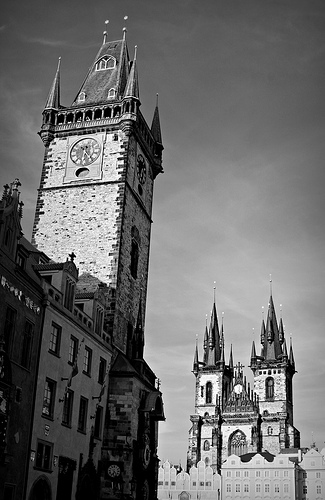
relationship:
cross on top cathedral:
[233, 361, 245, 377] [186, 270, 301, 472]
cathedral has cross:
[186, 270, 301, 472] [233, 361, 245, 377]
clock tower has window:
[29, 12, 167, 359] [123, 231, 142, 282]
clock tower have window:
[29, 12, 167, 359] [123, 231, 142, 282]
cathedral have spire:
[186, 270, 301, 472] [212, 279, 218, 305]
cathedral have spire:
[186, 270, 301, 472] [268, 272, 274, 298]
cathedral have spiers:
[186, 270, 301, 472] [122, 15, 129, 40]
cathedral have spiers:
[186, 270, 301, 472] [102, 19, 110, 44]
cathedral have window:
[12, 253, 187, 473] [35, 316, 74, 359]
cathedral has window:
[12, 253, 187, 473] [35, 316, 74, 359]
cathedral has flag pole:
[0, 25, 165, 499] [60, 337, 86, 406]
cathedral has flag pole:
[0, 25, 165, 499] [90, 347, 120, 401]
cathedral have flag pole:
[0, 25, 165, 499] [60, 337, 86, 406]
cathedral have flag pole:
[0, 25, 165, 499] [90, 347, 120, 401]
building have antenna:
[187, 297, 232, 469] [211, 286, 216, 305]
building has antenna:
[187, 297, 232, 469] [211, 286, 216, 305]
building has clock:
[34, 15, 165, 352] [69, 136, 102, 167]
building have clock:
[34, 15, 165, 352] [69, 136, 102, 167]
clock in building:
[69, 136, 102, 167] [34, 15, 165, 352]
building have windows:
[212, 441, 322, 498] [224, 470, 291, 497]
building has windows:
[212, 441, 322, 498] [224, 470, 291, 497]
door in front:
[227, 428, 247, 454] [187, 272, 284, 468]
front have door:
[187, 272, 284, 468] [227, 428, 247, 454]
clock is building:
[69, 136, 102, 167] [29, 15, 165, 356]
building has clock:
[29, 15, 165, 356] [69, 136, 102, 167]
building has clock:
[29, 15, 165, 356] [134, 154, 147, 185]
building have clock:
[29, 15, 165, 356] [69, 136, 102, 167]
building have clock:
[29, 15, 165, 356] [134, 154, 147, 185]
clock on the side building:
[135, 153, 152, 186] [29, 15, 165, 356]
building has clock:
[29, 15, 165, 356] [135, 153, 152, 186]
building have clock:
[29, 15, 165, 356] [135, 153, 152, 186]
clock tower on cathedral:
[29, 12, 167, 359] [0, 25, 165, 499]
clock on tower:
[60, 133, 104, 178] [50, 27, 167, 255]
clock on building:
[95, 458, 126, 478] [56, 204, 187, 482]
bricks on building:
[113, 400, 135, 439] [196, 335, 310, 445]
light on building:
[101, 13, 134, 37] [59, 87, 137, 283]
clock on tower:
[69, 136, 102, 167] [214, 357, 258, 471]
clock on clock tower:
[135, 153, 147, 186] [29, 12, 167, 359]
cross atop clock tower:
[232, 359, 247, 376] [180, 256, 302, 494]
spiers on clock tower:
[99, 10, 134, 45] [30, 12, 167, 311]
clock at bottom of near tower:
[107, 464, 121, 479] [6, 12, 174, 496]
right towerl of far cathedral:
[240, 259, 308, 464] [186, 270, 301, 472]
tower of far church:
[186, 279, 234, 472] [187, 272, 300, 469]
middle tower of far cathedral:
[220, 356, 253, 466] [186, 270, 301, 472]